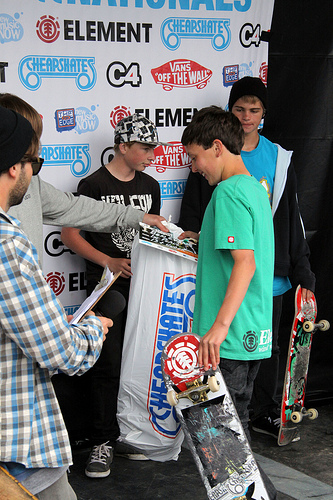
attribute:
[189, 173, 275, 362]
t-shirt — bright green, white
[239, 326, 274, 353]
writing — black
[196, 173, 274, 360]
green shirt — oversized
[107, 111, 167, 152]
hat — black, white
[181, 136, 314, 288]
shirt — blue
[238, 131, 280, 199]
shirt — gray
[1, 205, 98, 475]
shirt — white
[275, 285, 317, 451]
skateboard — red, green, black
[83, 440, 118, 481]
sneakers — grey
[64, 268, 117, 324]
paper — white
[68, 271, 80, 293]
letter — black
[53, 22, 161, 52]
letter — black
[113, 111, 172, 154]
hat — black, white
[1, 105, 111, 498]
man — blue, plaid, holding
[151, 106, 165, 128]
letter — black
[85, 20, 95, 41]
letter — black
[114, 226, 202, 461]
shopping bag — large, white, plastic, blue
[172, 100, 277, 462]
people — several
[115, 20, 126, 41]
letter — black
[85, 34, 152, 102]
letter — black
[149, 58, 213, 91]
advertisement — red, white, bright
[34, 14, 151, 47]
advertisement — white, red, bright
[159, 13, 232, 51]
advertisement — bright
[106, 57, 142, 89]
advertisement — bright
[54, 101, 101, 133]
advertisement — bright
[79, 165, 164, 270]
tshirt — black, white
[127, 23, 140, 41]
letter — black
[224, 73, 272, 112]
cap — black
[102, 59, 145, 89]
c4 — large, black, white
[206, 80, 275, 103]
skull cap — black, knit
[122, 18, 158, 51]
letter — black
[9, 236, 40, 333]
plaid — blue, white, grey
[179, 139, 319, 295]
sweatshirt — black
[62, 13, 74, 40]
letter — black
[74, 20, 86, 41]
letter — black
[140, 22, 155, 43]
letter — black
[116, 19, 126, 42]
letter — black